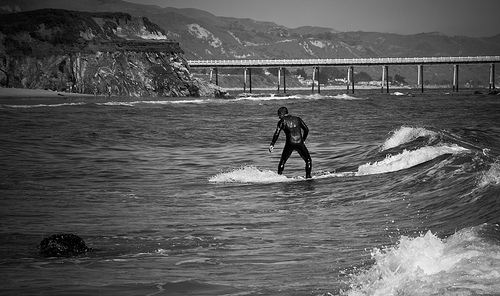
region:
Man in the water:
[252, 91, 320, 208]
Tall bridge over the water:
[181, 44, 497, 96]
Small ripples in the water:
[146, 259, 216, 294]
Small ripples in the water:
[213, 262, 270, 294]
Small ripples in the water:
[261, 253, 318, 293]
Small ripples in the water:
[293, 240, 351, 285]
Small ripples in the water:
[343, 245, 400, 284]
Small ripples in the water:
[397, 238, 452, 284]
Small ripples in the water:
[398, 183, 436, 232]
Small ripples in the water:
[315, 191, 378, 245]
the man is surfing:
[179, 82, 362, 207]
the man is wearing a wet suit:
[258, 118, 320, 179]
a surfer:
[265, 103, 321, 178]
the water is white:
[377, 140, 429, 176]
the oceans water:
[171, 208, 296, 272]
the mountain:
[176, 21, 245, 50]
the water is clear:
[81, 114, 186, 205]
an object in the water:
[40, 233, 97, 265]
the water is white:
[378, 238, 463, 294]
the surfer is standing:
[271, 98, 318, 183]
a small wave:
[378, 149, 458, 176]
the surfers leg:
[281, 143, 318, 177]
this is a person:
[248, 81, 350, 198]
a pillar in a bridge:
[190, 45, 226, 98]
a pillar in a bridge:
[230, 58, 263, 105]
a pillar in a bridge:
[265, 55, 303, 100]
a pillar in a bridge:
[302, 62, 343, 104]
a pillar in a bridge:
[337, 68, 372, 99]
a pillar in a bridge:
[371, 56, 402, 104]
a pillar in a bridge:
[402, 51, 433, 92]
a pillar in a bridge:
[444, 55, 478, 96]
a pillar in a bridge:
[472, 59, 494, 81]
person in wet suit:
[262, 99, 327, 184]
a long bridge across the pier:
[170, 45, 497, 95]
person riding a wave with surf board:
[223, 99, 364, 194]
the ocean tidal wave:
[214, 90, 495, 250]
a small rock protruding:
[26, 226, 104, 265]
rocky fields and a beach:
[0, 6, 202, 103]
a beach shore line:
[4, 79, 122, 106]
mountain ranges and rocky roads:
[161, 2, 496, 94]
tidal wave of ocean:
[347, 219, 497, 291]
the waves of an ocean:
[360, 122, 475, 184]